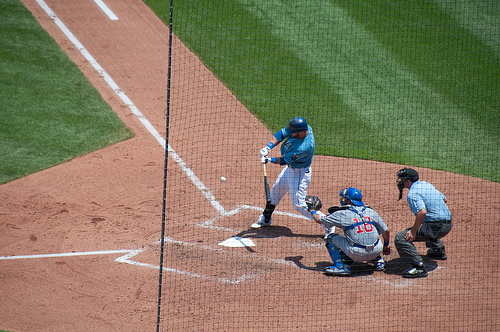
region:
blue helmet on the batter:
[284, 115, 309, 135]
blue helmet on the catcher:
[337, 185, 365, 206]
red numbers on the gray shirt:
[349, 214, 375, 234]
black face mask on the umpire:
[391, 165, 411, 200]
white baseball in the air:
[214, 173, 227, 183]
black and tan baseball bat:
[260, 159, 274, 206]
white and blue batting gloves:
[257, 140, 281, 163]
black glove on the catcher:
[301, 191, 323, 211]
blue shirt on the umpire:
[405, 178, 454, 221]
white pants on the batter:
[261, 163, 324, 224]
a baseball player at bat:
[249, 116, 335, 237]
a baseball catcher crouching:
[301, 187, 392, 274]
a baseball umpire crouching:
[392, 168, 454, 277]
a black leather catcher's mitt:
[304, 194, 321, 209]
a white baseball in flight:
[216, 174, 227, 183]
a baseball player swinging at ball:
[220, 115, 332, 237]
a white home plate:
[219, 234, 255, 245]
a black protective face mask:
[394, 165, 406, 201]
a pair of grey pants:
[393, 217, 454, 262]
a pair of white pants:
[268, 162, 323, 221]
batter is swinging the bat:
[243, 107, 308, 246]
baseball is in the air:
[209, 170, 233, 196]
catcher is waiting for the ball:
[297, 185, 382, 275]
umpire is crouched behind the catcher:
[391, 148, 455, 289]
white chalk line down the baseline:
[106, 81, 213, 221]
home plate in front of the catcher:
[216, 230, 268, 261]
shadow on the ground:
[240, 221, 301, 241]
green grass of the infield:
[6, 40, 67, 144]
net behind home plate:
[171, 32, 313, 272]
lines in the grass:
[273, 20, 479, 132]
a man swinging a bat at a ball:
[208, 110, 339, 241]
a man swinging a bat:
[247, 109, 334, 234]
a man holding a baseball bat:
[260, 148, 275, 206]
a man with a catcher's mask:
[392, 164, 407, 200]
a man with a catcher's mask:
[337, 186, 348, 207]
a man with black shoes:
[400, 267, 430, 280]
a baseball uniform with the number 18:
[318, 189, 395, 275]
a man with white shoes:
[250, 213, 277, 229]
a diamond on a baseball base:
[216, 233, 257, 252]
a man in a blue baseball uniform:
[272, 115, 320, 171]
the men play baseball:
[236, 80, 458, 287]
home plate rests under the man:
[216, 225, 252, 256]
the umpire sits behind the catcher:
[388, 164, 457, 281]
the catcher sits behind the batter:
[295, 174, 387, 286]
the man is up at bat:
[234, 95, 324, 245]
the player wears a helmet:
[284, 114, 308, 139]